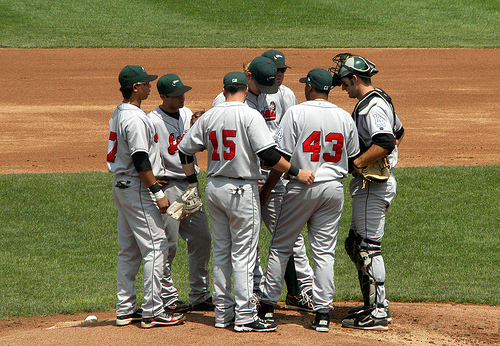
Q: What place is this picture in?
A: It is at the field.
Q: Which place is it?
A: It is a field.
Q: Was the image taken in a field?
A: Yes, it was taken in a field.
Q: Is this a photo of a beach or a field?
A: It is showing a field.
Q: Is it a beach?
A: No, it is a field.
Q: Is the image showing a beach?
A: No, the picture is showing a field.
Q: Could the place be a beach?
A: No, it is a field.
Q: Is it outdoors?
A: Yes, it is outdoors.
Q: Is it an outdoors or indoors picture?
A: It is outdoors.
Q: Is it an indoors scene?
A: No, it is outdoors.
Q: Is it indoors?
A: No, it is outdoors.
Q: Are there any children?
A: No, there are no children.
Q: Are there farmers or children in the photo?
A: No, there are no children or farmers.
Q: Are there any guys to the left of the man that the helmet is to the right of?
A: Yes, there is a guy to the left of the man.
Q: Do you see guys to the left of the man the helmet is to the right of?
A: Yes, there is a guy to the left of the man.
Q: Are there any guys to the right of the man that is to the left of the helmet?
A: No, the guy is to the left of the man.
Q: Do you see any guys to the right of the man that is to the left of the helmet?
A: No, the guy is to the left of the man.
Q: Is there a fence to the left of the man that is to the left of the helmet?
A: No, there is a guy to the left of the man.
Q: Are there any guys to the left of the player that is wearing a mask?
A: Yes, there is a guy to the left of the player.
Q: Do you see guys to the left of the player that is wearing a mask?
A: Yes, there is a guy to the left of the player.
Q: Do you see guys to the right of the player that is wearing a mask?
A: No, the guy is to the left of the player.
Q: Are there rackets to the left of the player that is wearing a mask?
A: No, there is a guy to the left of the player.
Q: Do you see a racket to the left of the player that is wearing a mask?
A: No, there is a guy to the left of the player.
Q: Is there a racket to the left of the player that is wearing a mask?
A: No, there is a guy to the left of the player.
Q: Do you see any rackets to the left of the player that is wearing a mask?
A: No, there is a guy to the left of the player.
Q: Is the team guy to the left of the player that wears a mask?
A: Yes, the guy is to the left of the player.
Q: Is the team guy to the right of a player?
A: No, the guy is to the left of a player.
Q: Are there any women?
A: No, there are no women.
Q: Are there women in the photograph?
A: No, there are no women.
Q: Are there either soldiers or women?
A: No, there are no women or soldiers.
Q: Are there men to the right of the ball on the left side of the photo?
A: Yes, there is a man to the right of the ball.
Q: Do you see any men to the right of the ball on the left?
A: Yes, there is a man to the right of the ball.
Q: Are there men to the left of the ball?
A: No, the man is to the right of the ball.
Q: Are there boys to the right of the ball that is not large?
A: No, there is a man to the right of the ball.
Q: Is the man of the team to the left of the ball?
A: No, the man is to the right of the ball.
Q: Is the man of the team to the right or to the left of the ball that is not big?
A: The man is to the right of the ball.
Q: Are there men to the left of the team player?
A: Yes, there is a man to the left of the player.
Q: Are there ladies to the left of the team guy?
A: No, there is a man to the left of the guy.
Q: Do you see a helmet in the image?
A: Yes, there is a helmet.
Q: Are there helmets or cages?
A: Yes, there is a helmet.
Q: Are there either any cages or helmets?
A: Yes, there is a helmet.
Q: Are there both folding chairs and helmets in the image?
A: No, there is a helmet but no folding chairs.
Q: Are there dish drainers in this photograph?
A: No, there are no dish drainers.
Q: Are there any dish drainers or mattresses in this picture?
A: No, there are no dish drainers or mattresses.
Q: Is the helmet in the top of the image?
A: Yes, the helmet is in the top of the image.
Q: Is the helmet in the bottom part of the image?
A: No, the helmet is in the top of the image.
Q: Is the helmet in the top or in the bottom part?
A: The helmet is in the top of the image.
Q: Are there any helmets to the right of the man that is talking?
A: Yes, there is a helmet to the right of the man.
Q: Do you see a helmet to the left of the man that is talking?
A: No, the helmet is to the right of the man.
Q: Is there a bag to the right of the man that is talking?
A: No, there is a helmet to the right of the man.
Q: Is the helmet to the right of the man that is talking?
A: Yes, the helmet is to the right of the man.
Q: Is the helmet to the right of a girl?
A: No, the helmet is to the right of the man.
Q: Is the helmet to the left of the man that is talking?
A: No, the helmet is to the right of the man.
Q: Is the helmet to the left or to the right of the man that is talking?
A: The helmet is to the right of the man.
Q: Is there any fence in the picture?
A: No, there are no fences.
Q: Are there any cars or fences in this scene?
A: No, there are no fences or cars.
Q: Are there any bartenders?
A: No, there are no bartenders.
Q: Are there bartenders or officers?
A: No, there are no bartenders or officers.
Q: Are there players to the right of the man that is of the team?
A: Yes, there is a player to the right of the man.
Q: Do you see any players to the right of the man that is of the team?
A: Yes, there is a player to the right of the man.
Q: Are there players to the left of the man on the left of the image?
A: No, the player is to the right of the man.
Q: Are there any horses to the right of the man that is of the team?
A: No, there is a player to the right of the man.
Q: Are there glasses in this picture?
A: No, there are no glasses.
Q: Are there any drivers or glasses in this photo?
A: No, there are no glasses or drivers.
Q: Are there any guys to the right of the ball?
A: Yes, there is a guy to the right of the ball.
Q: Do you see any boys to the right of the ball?
A: No, there is a guy to the right of the ball.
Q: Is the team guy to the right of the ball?
A: Yes, the guy is to the right of the ball.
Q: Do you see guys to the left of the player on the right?
A: Yes, there is a guy to the left of the player.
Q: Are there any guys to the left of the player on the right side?
A: Yes, there is a guy to the left of the player.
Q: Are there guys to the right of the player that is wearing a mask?
A: No, the guy is to the left of the player.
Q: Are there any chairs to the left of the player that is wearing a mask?
A: No, there is a guy to the left of the player.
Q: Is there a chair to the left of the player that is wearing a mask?
A: No, there is a guy to the left of the player.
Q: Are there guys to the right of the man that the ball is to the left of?
A: Yes, there is a guy to the right of the man.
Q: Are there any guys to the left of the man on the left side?
A: No, the guy is to the right of the man.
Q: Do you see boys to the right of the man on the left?
A: No, there is a guy to the right of the man.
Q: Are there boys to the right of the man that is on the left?
A: No, there is a guy to the right of the man.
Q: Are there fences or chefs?
A: No, there are no fences or chefs.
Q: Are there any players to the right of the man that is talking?
A: Yes, there is a player to the right of the man.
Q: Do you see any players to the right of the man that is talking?
A: Yes, there is a player to the right of the man.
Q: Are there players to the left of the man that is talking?
A: No, the player is to the right of the man.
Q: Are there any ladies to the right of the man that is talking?
A: No, there is a player to the right of the man.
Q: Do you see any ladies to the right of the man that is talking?
A: No, there is a player to the right of the man.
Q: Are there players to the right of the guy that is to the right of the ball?
A: Yes, there is a player to the right of the guy.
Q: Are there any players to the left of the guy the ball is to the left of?
A: No, the player is to the right of the guy.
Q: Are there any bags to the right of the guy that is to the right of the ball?
A: No, there is a player to the right of the guy.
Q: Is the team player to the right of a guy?
A: Yes, the player is to the right of a guy.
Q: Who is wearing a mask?
A: The player is wearing a mask.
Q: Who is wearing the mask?
A: The player is wearing a mask.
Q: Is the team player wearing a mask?
A: Yes, the player is wearing a mask.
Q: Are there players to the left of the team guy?
A: No, the player is to the right of the guy.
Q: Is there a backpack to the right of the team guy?
A: No, there is a player to the right of the guy.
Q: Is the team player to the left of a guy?
A: No, the player is to the right of a guy.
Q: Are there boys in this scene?
A: No, there are no boys.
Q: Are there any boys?
A: No, there are no boys.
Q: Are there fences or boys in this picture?
A: No, there are no boys or fences.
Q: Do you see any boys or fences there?
A: No, there are no boys or fences.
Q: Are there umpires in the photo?
A: No, there are no umpires.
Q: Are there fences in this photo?
A: No, there are no fences.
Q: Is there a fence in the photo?
A: No, there are no fences.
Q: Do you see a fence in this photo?
A: No, there are no fences.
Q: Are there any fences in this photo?
A: No, there are no fences.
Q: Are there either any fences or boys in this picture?
A: No, there are no fences or boys.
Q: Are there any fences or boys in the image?
A: No, there are no boys or fences.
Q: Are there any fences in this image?
A: No, there are no fences.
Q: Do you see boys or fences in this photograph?
A: No, there are no fences or boys.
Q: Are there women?
A: No, there are no women.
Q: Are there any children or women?
A: No, there are no women or children.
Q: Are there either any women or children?
A: No, there are no women or children.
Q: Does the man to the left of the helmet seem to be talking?
A: Yes, the man is talking.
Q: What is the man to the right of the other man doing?
A: The man is talking.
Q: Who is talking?
A: The man is talking.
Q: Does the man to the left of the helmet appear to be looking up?
A: No, the man is talking.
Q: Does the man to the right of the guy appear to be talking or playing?
A: The man is talking.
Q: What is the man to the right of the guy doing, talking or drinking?
A: The man is talking.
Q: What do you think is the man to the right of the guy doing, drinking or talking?
A: The man is talking.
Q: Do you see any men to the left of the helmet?
A: Yes, there is a man to the left of the helmet.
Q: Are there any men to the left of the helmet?
A: Yes, there is a man to the left of the helmet.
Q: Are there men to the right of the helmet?
A: No, the man is to the left of the helmet.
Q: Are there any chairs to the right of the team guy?
A: No, there is a man to the right of the guy.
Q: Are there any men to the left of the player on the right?
A: Yes, there is a man to the left of the player.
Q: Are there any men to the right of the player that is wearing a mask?
A: No, the man is to the left of the player.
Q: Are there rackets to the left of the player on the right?
A: No, there is a man to the left of the player.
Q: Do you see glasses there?
A: No, there are no glasses.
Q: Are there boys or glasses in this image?
A: No, there are no glasses or boys.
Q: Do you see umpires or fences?
A: No, there are no fences or umpires.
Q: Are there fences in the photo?
A: No, there are no fences.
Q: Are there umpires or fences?
A: No, there are no fences or umpires.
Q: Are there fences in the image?
A: No, there are no fences.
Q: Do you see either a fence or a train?
A: No, there are no fences or trains.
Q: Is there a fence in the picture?
A: No, there are no fences.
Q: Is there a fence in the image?
A: No, there are no fences.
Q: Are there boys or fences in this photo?
A: No, there are no fences or boys.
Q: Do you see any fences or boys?
A: No, there are no fences or boys.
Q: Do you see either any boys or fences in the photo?
A: No, there are no fences or boys.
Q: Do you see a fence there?
A: No, there are no fences.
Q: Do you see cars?
A: No, there are no cars.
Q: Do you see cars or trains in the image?
A: No, there are no cars or trains.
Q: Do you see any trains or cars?
A: No, there are no cars or trains.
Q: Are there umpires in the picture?
A: No, there are no umpires.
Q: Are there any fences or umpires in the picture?
A: No, there are no umpires or fences.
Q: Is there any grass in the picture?
A: Yes, there is grass.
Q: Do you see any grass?
A: Yes, there is grass.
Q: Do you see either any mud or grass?
A: Yes, there is grass.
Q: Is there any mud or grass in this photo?
A: Yes, there is grass.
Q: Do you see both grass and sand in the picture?
A: No, there is grass but no sand.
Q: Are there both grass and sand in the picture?
A: No, there is grass but no sand.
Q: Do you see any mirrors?
A: No, there are no mirrors.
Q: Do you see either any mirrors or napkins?
A: No, there are no mirrors or napkins.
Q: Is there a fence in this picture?
A: No, there are no fences.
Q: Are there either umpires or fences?
A: No, there are no fences or umpires.